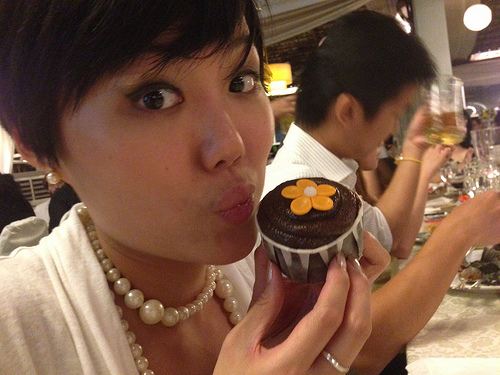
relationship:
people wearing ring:
[0, 0, 378, 375] [315, 348, 347, 373]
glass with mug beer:
[425, 75, 472, 147] [420, 108, 469, 146]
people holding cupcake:
[0, 0, 378, 375] [260, 180, 362, 264]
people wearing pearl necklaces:
[0, 0, 378, 375] [84, 223, 217, 326]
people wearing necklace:
[0, 0, 378, 375] [80, 207, 268, 373]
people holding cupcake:
[0, 0, 378, 375] [256, 177, 364, 284]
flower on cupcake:
[280, 179, 336, 215] [256, 177, 364, 284]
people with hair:
[0, 0, 378, 375] [2, 6, 272, 170]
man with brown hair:
[258, 16, 446, 211] [295, 24, 434, 99]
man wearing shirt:
[258, 3, 459, 375] [261, 10, 442, 220]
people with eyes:
[0, 0, 378, 375] [111, 63, 273, 114]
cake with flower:
[259, 173, 368, 277] [280, 178, 337, 216]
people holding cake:
[0, 0, 378, 375] [253, 175, 365, 287]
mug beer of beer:
[416, 75, 469, 153] [428, 172, 458, 203]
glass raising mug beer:
[425, 75, 468, 148] [420, 108, 469, 146]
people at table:
[0, 0, 499, 372] [393, 242, 500, 372]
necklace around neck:
[81, 217, 261, 366] [73, 222, 232, 301]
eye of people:
[132, 79, 188, 115] [0, 0, 378, 375]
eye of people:
[224, 68, 261, 100] [0, 0, 378, 375]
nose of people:
[179, 96, 269, 186] [0, 0, 378, 375]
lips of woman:
[210, 182, 255, 227] [14, 54, 340, 364]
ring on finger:
[319, 345, 351, 371] [291, 250, 373, 372]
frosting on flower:
[273, 176, 340, 215] [277, 173, 339, 215]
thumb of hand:
[219, 254, 288, 351] [202, 248, 375, 373]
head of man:
[293, 11, 438, 162] [261, 9, 447, 198]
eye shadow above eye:
[119, 81, 183, 97] [122, 80, 189, 114]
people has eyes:
[0, 0, 378, 375] [121, 47, 266, 121]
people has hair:
[0, 0, 378, 375] [2, 6, 272, 170]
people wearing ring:
[0, 0, 378, 375] [324, 351, 351, 373]